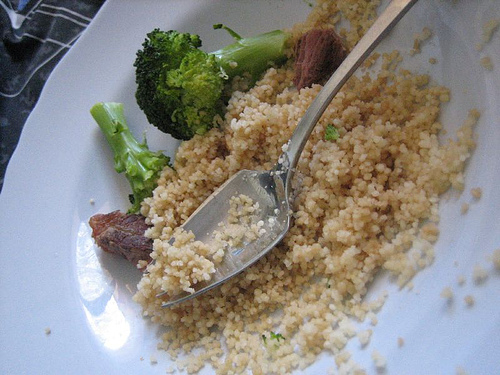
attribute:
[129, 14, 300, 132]
florets — green, broccoli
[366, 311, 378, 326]
cous cous — tiny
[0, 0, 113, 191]
mat — black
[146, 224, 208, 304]
cous cous — tiny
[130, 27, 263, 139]
broccoli — green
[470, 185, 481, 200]
cous cous — tiny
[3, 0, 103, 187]
cloth — grey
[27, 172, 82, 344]
plate — white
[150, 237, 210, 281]
cous cous — tiny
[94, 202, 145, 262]
meat piece — maroon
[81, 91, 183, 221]
vegetable — green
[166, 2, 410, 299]
spoon — metal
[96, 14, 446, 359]
food — appetizing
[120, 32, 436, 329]
food — brown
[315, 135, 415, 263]
cous cous — tiny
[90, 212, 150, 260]
steak — brown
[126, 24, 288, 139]
vegetable — green